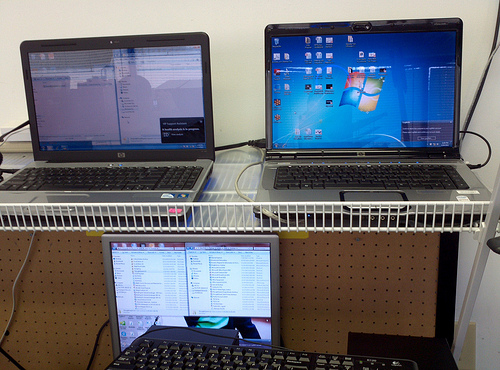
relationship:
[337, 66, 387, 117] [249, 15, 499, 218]
logo on desktop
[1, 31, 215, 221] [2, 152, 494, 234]
laptop on shelf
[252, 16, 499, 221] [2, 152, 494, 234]
laptop on shelf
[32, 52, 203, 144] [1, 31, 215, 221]
background of laptop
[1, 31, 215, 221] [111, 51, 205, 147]
laptop with windows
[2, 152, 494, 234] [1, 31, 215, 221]
shelf has laptop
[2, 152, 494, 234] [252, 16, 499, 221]
shelf has laptop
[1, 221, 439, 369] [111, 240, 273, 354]
pegboard behind screen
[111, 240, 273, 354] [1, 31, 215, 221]
screen under laptop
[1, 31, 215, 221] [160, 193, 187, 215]
laptop has stickers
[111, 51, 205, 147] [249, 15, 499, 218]
windows on desktop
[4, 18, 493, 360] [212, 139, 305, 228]
computers have wires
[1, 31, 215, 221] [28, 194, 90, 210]
laptop with mouse pad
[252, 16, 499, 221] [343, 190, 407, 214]
laptop with mouse pad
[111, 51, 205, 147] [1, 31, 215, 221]
windows on laptop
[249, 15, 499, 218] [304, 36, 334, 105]
desktop with icons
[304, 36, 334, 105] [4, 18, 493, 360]
icons on computers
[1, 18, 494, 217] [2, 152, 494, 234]
laptops on shelf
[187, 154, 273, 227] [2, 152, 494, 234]
plastic liner on shelf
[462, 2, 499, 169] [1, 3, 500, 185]
cord up wall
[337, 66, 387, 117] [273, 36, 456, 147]
logo on screen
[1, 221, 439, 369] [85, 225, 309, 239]
pegboard has tape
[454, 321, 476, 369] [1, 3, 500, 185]
switch on wall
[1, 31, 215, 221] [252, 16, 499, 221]
laptop next to laptop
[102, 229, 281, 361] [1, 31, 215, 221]
laptop below laptop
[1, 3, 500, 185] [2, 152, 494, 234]
wall behind shelf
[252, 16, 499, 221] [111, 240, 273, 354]
laptop with screen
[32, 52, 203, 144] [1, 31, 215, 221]
background on laptop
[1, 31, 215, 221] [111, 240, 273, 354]
laptop with computer screen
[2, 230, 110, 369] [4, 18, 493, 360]
wire near computers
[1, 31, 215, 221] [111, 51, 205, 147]
laptop with silver windows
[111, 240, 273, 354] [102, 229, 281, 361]
screen of laptop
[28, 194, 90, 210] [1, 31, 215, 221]
mouse pad of laptop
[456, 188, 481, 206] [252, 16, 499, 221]
labels on laptop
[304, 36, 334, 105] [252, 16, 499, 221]
icons on laptop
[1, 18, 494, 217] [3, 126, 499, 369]
laptops on display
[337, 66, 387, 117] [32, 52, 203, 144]
logo on background